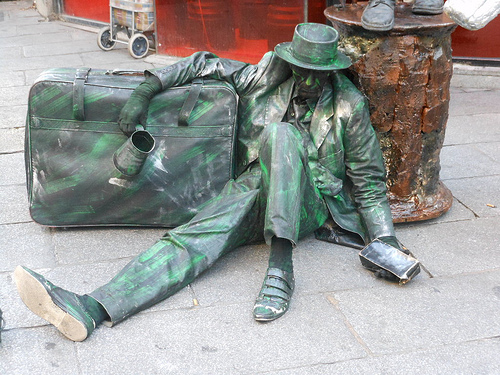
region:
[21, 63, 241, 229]
Green and gray suitcase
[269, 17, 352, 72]
Green and gray hat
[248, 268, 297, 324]
Green and grey shoe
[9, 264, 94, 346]
White sole of a shoe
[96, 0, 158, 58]
Cart with two white wheels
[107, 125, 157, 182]
Green and gray mug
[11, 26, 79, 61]
Sidewalk made up of gray squares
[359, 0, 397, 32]
Dirty black shoe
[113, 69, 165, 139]
Green and gray glove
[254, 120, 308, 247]
Green and gray pantleg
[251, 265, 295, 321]
painted shoe of person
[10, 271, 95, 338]
painted shoe of person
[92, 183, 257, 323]
painted pant leg of person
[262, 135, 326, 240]
painted pant leg of person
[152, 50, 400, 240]
painted jacket of person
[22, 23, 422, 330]
painted person acting like statue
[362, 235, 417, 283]
painted item in hand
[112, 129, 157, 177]
painted can in hand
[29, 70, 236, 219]
painted suitcae by person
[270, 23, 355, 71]
painted hat of person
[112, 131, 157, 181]
A beggar's coffee can.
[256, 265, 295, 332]
A worn out green shoe.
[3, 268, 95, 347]
The sole of a second green shoe.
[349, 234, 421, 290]
A small black box.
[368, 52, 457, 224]
A pedestal shaped like a tree stump.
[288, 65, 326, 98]
The face of a statue.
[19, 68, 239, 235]
A large, green travel bag.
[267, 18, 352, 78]
A green fedora hat.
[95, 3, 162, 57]
The lower portion of a stroller.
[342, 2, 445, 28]
A pair of worn shoes.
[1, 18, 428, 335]
a statue of a man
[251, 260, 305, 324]
the shoe of a statue of a man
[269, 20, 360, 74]
the hat of a statue of a man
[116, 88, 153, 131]
the hand of a statue of a man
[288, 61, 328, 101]
the face of a statue of a man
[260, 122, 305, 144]
the knee of a statue of a man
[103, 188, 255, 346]
the leg of a statue of a man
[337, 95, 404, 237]
the arm of a statue of a man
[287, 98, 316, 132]
the tie of a statue of a man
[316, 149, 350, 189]
the pocket of a statue of a man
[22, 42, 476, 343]
Man dressed as a statue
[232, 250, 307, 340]
Man is wearing shoes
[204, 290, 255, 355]
Cement tile on the ground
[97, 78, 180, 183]
Man holding a cup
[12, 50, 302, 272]
Suitcase beside the man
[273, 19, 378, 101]
man wearing a hat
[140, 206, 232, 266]
Wrinkles in the pants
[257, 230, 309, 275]
Socks on the man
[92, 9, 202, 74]
Cart on the ground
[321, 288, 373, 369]
Crack in the ground